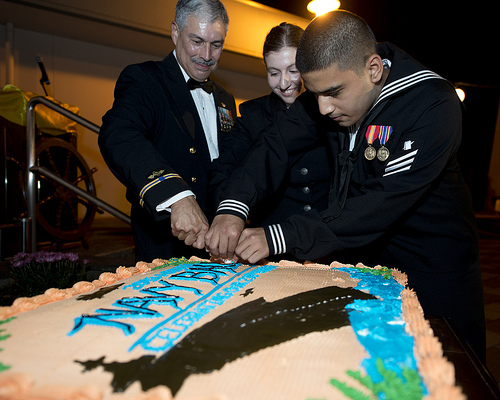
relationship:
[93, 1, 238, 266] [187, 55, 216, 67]
man has mustache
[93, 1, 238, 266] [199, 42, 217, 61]
man has nose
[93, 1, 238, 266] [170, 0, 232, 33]
man has hair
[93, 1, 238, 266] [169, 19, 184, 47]
man has ear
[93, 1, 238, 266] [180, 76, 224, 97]
man wears tie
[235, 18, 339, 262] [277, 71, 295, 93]
woman has nose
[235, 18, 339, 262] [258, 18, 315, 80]
woman has hair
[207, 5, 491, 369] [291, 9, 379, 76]
man has hair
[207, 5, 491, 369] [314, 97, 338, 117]
man has nose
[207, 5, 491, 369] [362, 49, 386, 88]
man has ear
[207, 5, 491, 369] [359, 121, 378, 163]
man has medal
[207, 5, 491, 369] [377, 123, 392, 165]
man has medal